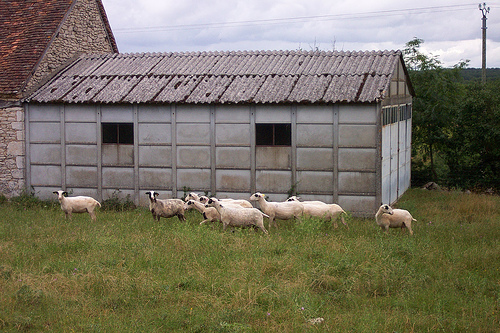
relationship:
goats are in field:
[52, 186, 417, 236] [1, 188, 498, 330]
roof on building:
[22, 48, 416, 108] [38, 39, 411, 229]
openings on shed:
[92, 118, 304, 153] [24, 48, 414, 213]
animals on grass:
[39, 174, 425, 243] [343, 234, 461, 286]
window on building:
[251, 118, 296, 152] [22, 41, 415, 218]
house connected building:
[0, 0, 117, 202] [22, 41, 415, 218]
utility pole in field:
[473, 1, 498, 71] [1, 188, 498, 330]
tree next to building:
[407, 50, 464, 191] [22, 41, 415, 218]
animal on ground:
[368, 196, 425, 243] [6, 180, 484, 330]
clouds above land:
[209, 9, 363, 44] [8, 188, 484, 328]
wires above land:
[113, 1, 484, 40] [2, 230, 497, 327]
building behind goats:
[0, 1, 422, 234] [55, 182, 421, 241]